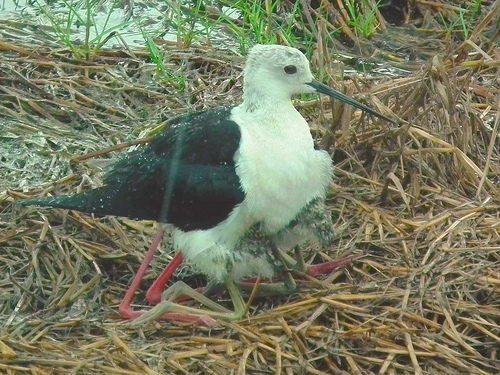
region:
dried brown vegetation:
[367, 62, 497, 373]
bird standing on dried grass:
[23, 43, 397, 334]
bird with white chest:
[37, 43, 317, 255]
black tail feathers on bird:
[26, 45, 314, 272]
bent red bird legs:
[112, 223, 214, 329]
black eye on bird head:
[237, 43, 307, 109]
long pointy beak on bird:
[242, 42, 397, 127]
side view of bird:
[35, 42, 393, 320]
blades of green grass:
[27, 5, 429, 70]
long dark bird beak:
[244, 41, 395, 126]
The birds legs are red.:
[139, 236, 171, 296]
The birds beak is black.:
[309, 72, 397, 132]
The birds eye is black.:
[283, 57, 298, 78]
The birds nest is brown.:
[383, 193, 457, 247]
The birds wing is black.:
[141, 154, 211, 207]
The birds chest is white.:
[259, 110, 295, 176]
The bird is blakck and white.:
[158, 144, 299, 191]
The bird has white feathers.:
[267, 128, 305, 177]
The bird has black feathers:
[170, 133, 219, 183]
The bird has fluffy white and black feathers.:
[207, 122, 283, 182]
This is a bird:
[23, 34, 478, 340]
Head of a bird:
[243, 26, 415, 147]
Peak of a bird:
[306, 58, 428, 143]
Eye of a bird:
[277, 54, 299, 87]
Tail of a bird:
[2, 172, 127, 247]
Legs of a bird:
[203, 228, 288, 370]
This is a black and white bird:
[26, 41, 446, 313]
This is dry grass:
[331, 161, 481, 361]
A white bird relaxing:
[23, 35, 473, 361]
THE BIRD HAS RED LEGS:
[79, 203, 377, 332]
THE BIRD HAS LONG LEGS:
[103, 218, 377, 342]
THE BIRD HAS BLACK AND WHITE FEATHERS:
[17, 38, 407, 328]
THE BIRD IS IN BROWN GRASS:
[5, 0, 495, 372]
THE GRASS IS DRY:
[3, 0, 498, 373]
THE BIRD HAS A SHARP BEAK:
[306, 76, 405, 125]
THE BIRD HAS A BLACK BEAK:
[305, 77, 400, 129]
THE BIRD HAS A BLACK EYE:
[273, 58, 300, 83]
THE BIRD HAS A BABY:
[127, 198, 343, 340]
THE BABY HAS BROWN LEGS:
[131, 259, 304, 336]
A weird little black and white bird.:
[21, 27, 400, 309]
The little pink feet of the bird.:
[107, 244, 217, 324]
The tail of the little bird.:
[3, 169, 105, 234]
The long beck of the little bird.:
[308, 65, 405, 147]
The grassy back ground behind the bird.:
[11, 4, 171, 96]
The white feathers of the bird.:
[247, 124, 329, 193]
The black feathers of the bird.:
[141, 157, 227, 216]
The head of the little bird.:
[235, 31, 406, 126]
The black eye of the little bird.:
[280, 60, 301, 80]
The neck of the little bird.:
[235, 84, 304, 107]